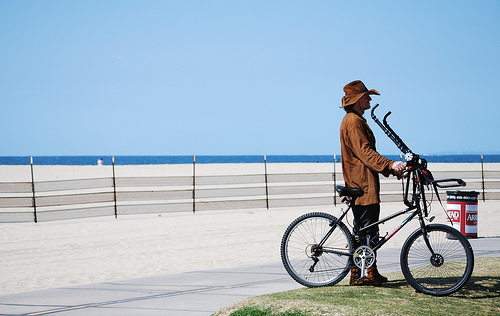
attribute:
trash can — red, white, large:
[443, 190, 486, 248]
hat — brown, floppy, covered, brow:
[332, 76, 383, 108]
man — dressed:
[333, 74, 398, 284]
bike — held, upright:
[278, 162, 478, 302]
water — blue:
[38, 152, 115, 164]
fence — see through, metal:
[29, 157, 291, 211]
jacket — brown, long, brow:
[333, 111, 393, 208]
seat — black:
[336, 182, 366, 201]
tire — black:
[401, 223, 475, 299]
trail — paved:
[2, 243, 496, 311]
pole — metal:
[186, 154, 207, 214]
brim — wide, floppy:
[367, 82, 382, 102]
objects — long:
[369, 100, 443, 194]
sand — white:
[91, 230, 169, 262]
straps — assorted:
[413, 168, 446, 223]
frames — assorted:
[394, 150, 465, 216]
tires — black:
[278, 214, 480, 295]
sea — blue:
[36, 154, 95, 162]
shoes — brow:
[351, 267, 394, 284]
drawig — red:
[446, 199, 474, 234]